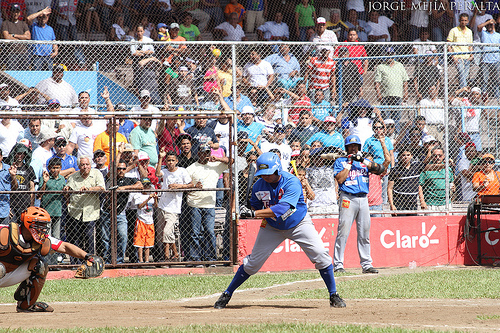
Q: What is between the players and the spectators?
A: A fence.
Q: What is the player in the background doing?
A: Waiting to hit the ball.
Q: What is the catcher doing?
A: Waiting to catch the ball.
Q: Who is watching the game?
A: Fans.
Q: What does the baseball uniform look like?
A: Blue and gray.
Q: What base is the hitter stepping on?
A: Home plate.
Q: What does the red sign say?
A: Claro.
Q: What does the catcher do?
A: Catch the ball.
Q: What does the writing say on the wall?
A: Claro.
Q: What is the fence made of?
A: Chain link.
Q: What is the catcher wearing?
A: A catcher's mask.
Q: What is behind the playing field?
A: Fans of the game.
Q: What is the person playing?
A: Baseball.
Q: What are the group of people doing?
A: Watching the game.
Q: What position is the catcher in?
A: Crouched down.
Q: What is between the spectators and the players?
A: A fence.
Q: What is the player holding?
A: Bat.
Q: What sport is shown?
A: Baseball.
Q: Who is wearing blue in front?
A: The batter.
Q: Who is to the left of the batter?
A: Catcher.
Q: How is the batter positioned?
A: Legs apart with the bat over his right shoulder.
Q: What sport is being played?
A: Baseball.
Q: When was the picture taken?
A: During the day.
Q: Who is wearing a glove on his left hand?
A: The catcher.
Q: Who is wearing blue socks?
A: The batter.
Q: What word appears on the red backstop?
A: Claro.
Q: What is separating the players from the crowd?
A: A chain link fence.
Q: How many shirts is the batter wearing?
A: Two.